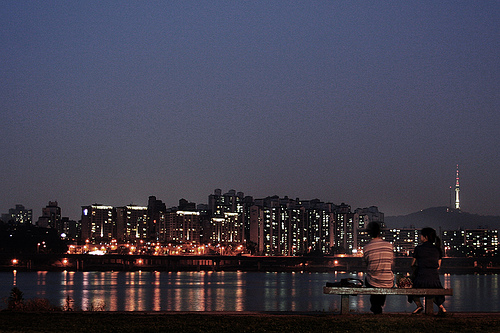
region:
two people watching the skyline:
[39, 100, 491, 277]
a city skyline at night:
[47, 157, 336, 264]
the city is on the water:
[23, 131, 353, 324]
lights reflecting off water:
[59, 173, 228, 330]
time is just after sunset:
[25, 17, 401, 319]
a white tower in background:
[416, 123, 487, 245]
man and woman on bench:
[291, 197, 492, 300]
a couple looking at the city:
[188, 160, 482, 310]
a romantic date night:
[43, 46, 481, 321]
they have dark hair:
[343, 202, 485, 326]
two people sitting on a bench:
[312, 205, 477, 320]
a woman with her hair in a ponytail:
[402, 209, 447, 257]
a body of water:
[96, 276, 316, 301]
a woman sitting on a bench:
[405, 211, 456, 307]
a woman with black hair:
[408, 216, 441, 262]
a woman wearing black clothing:
[408, 223, 443, 299]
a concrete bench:
[318, 285, 453, 317]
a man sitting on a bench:
[348, 221, 400, 291]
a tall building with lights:
[433, 153, 473, 218]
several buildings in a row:
[62, 177, 362, 263]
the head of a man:
[359, 211, 412, 250]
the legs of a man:
[360, 273, 387, 318]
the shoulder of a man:
[351, 238, 383, 265]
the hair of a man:
[359, 217, 386, 251]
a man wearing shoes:
[362, 285, 397, 319]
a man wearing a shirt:
[329, 210, 433, 315]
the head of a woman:
[413, 208, 465, 250]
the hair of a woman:
[414, 213, 457, 253]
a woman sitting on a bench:
[404, 223, 459, 300]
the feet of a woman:
[408, 285, 481, 325]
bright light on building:
[104, 206, 116, 216]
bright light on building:
[123, 209, 134, 221]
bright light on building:
[137, 212, 155, 229]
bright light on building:
[127, 205, 142, 216]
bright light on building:
[76, 208, 93, 220]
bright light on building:
[93, 198, 120, 222]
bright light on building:
[177, 204, 194, 223]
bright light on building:
[209, 213, 224, 226]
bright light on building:
[232, 202, 245, 219]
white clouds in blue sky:
[248, 58, 293, 108]